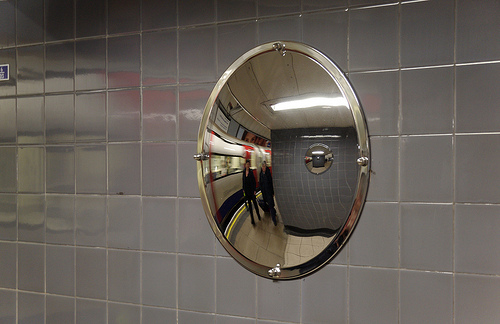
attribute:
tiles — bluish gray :
[404, 135, 472, 203]